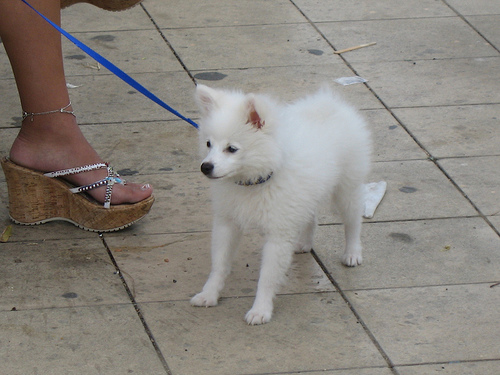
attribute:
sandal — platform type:
[21, 140, 176, 256]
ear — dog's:
[234, 92, 281, 137]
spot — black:
[191, 66, 228, 83]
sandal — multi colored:
[4, 151, 139, 238]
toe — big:
[110, 181, 151, 203]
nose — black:
[195, 154, 223, 187]